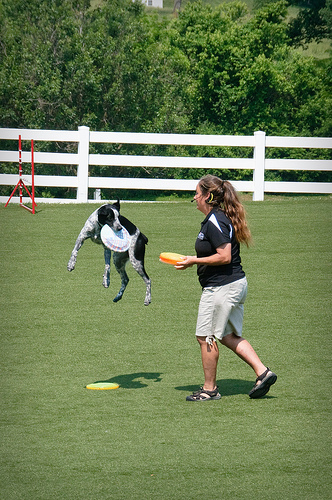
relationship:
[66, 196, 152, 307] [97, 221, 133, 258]
dog has frisbee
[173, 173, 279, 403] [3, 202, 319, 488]
woman on grass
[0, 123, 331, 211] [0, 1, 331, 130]
fence below trees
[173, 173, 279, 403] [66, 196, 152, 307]
woman near dog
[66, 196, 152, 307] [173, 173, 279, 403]
dog near woman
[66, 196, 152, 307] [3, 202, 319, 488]
dog on grass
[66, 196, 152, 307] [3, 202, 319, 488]
dog above grass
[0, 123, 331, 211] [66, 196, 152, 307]
fence behind dog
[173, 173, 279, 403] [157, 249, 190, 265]
woman tossing frisbee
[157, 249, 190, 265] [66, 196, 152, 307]
frisbee being tossed to dog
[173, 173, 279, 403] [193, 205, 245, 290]
woman wearing shirt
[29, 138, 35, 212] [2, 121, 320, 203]
pole standing next to fence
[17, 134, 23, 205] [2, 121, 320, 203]
pole standing next to fence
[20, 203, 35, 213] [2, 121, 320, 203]
pole standing next to fence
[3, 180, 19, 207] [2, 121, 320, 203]
pole standing next to fence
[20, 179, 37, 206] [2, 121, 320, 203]
pole standing next to fence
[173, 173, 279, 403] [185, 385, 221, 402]
woman wearing sandal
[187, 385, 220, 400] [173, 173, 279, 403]
foot belonging to woman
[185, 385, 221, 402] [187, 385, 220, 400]
sandal covering foot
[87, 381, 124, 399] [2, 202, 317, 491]
frisbee on ground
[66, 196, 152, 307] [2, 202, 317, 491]
dog on ground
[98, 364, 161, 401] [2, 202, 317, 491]
shadow on ground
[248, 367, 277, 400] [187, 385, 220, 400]
sandal on foot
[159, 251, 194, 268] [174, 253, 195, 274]
frisbee in hands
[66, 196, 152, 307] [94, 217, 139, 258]
dog catching frisbee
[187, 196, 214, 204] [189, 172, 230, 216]
microphone on head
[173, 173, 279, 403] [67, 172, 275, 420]
woman performing tricks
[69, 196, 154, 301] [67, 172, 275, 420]
dog performing tricks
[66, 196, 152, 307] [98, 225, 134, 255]
dog catching frisbee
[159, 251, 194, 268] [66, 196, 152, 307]
frisbee to dog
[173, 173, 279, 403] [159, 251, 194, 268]
woman throwing frisbee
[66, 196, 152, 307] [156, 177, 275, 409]
dog with trainer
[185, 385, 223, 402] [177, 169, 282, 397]
sandal on trainer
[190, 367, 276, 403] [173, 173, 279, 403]
sandal on woman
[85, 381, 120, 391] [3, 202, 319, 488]
frisbee on grass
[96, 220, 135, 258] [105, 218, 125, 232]
frisbee in mouth